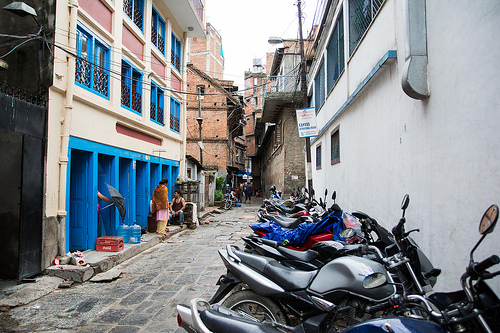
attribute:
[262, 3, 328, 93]
wires — hanging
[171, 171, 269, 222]
people — roaming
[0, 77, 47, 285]
gate — closed, black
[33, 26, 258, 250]
building — blue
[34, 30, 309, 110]
wires — electrical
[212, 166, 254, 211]
people — down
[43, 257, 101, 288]
sidewalk — cracked, dilapidated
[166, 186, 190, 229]
man — sitting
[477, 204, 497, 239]
mirror — round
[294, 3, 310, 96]
wood pole — electrical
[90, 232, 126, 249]
crates — red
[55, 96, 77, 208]
pipe — cream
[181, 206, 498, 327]
motorcycle — in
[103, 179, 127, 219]
umbrella — black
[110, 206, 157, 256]
water bottles — large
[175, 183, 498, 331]
motorcycles — parked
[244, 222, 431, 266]
bike — parked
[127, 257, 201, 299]
stone built — road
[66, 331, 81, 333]
brick — red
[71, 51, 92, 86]
window — blue